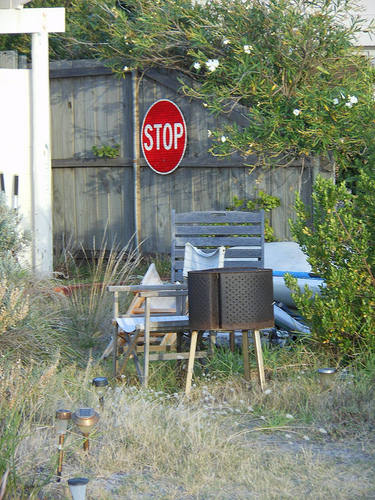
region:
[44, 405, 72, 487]
Small solar path light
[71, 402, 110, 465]
Small solar path light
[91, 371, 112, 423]
Small solar path light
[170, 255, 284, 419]
Fire pit with three legs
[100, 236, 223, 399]
Wooden and canvas chair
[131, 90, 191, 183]
Red and white sign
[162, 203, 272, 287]
Wooden backed chair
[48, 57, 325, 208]
Stop sign mounted on a fence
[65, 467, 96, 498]
Small solar path light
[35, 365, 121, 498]
Group of solar path lights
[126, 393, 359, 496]
grass is strawlike and dying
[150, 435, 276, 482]
grass is strawlike and dying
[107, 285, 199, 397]
chair has blue seat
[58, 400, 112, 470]
light stick stuck in ground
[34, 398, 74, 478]
light stick stuck in ground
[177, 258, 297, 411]
black grill on wood post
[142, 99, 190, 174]
a red stop sign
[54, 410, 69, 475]
a brown light on the ground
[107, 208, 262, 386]
a wooden chair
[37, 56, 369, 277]
a wooden fence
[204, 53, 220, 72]
white flowers in the bush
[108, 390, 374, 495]
weeds on the ground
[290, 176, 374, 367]
a bush next to the chair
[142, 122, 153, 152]
Letter S of STOP sign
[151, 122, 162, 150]
Letter T of STOP sign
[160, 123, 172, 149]
Letter O of STOP sign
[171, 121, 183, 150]
Letter P of stop sign